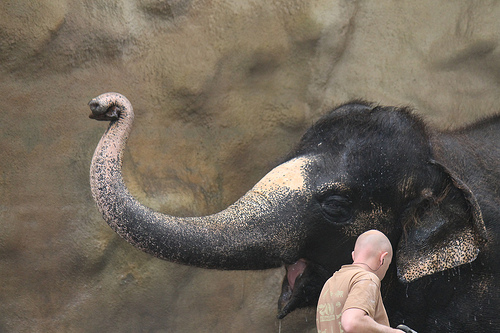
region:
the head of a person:
[352, 229, 392, 274]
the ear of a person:
[351, 248, 355, 259]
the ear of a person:
[377, 252, 387, 264]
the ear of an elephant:
[392, 154, 488, 274]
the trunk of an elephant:
[80, 93, 305, 270]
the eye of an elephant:
[322, 187, 349, 218]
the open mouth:
[277, 254, 320, 305]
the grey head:
[293, 101, 439, 303]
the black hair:
[310, 99, 436, 179]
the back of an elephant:
[427, 112, 497, 161]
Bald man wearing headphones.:
[315, 230, 419, 330]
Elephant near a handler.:
[89, 87, 488, 332]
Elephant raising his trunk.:
[86, 90, 486, 331]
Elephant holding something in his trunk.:
[88, 80, 486, 331]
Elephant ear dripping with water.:
[395, 163, 483, 286]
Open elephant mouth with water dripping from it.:
[276, 258, 316, 323]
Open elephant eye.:
[318, 183, 356, 224]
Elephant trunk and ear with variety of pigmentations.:
[85, 93, 487, 316]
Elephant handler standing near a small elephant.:
[319, 222, 426, 332]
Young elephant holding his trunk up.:
[86, 92, 482, 331]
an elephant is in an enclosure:
[10, 6, 489, 330]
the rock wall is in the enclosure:
[5, 8, 495, 330]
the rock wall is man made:
[8, 6, 494, 326]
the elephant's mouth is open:
[250, 235, 317, 323]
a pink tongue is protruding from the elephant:
[282, 253, 308, 287]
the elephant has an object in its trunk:
[72, 83, 139, 153]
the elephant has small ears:
[392, 149, 494, 287]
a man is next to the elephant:
[307, 225, 408, 331]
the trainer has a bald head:
[346, 223, 398, 283]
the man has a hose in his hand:
[315, 227, 419, 332]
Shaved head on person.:
[345, 223, 401, 288]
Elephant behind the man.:
[75, 70, 499, 332]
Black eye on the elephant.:
[317, 187, 351, 219]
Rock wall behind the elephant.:
[1, 3, 498, 329]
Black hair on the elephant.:
[287, 86, 439, 177]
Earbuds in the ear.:
[332, 223, 396, 277]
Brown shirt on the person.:
[310, 223, 397, 332]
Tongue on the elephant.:
[280, 252, 307, 286]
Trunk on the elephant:
[82, 78, 356, 280]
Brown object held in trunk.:
[85, 85, 128, 127]